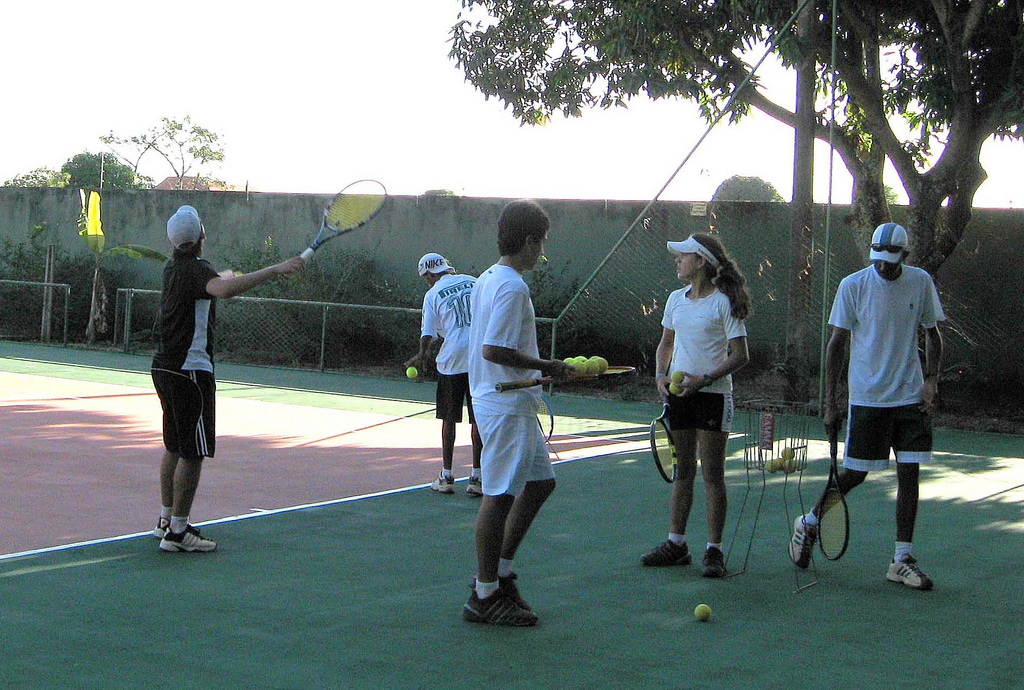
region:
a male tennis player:
[459, 199, 638, 627]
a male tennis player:
[399, 249, 479, 494]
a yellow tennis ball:
[691, 603, 712, 622]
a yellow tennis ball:
[667, 366, 684, 383]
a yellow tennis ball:
[668, 380, 681, 393]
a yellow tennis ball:
[592, 356, 606, 372]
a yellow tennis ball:
[574, 357, 588, 376]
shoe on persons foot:
[145, 509, 171, 539]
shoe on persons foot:
[454, 579, 537, 627]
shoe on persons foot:
[498, 565, 527, 607]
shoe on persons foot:
[701, 544, 728, 580]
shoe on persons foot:
[885, 549, 936, 594]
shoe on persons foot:
[429, 468, 456, 494]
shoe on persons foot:
[460, 468, 486, 500]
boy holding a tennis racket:
[151, 178, 390, 553]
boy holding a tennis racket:
[468, 200, 634, 625]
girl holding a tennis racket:
[643, 228, 745, 570]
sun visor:
[666, 235, 721, 265]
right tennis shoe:
[638, 535, 690, 568]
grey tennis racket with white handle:
[303, 178, 390, 255]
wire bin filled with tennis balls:
[724, 398, 823, 591]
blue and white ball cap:
[868, 219, 907, 262]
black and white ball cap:
[417, 252, 453, 273]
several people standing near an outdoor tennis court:
[3, 2, 1016, 688]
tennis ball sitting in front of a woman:
[640, 230, 754, 624]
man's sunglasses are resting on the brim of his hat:
[787, 222, 946, 590]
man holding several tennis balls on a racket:
[464, 200, 641, 625]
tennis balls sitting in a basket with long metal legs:
[717, 397, 822, 591]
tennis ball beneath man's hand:
[400, 252, 483, 494]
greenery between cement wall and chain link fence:
[3, 185, 1022, 433]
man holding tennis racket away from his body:
[149, 176, 388, 551]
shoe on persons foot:
[149, 519, 219, 552]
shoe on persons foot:
[148, 509, 168, 533]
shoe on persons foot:
[458, 578, 532, 629]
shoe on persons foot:
[502, 569, 528, 611]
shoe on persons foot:
[430, 464, 456, 491]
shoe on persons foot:
[697, 541, 729, 576]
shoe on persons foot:
[879, 554, 933, 596]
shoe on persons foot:
[464, 462, 488, 500]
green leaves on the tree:
[667, 40, 712, 83]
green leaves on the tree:
[509, 10, 557, 75]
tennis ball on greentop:
[693, 589, 716, 625]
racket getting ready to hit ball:
[307, 174, 393, 261]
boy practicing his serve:
[398, 247, 488, 486]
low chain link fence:
[125, 279, 556, 381]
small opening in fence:
[63, 276, 130, 362]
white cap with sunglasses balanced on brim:
[854, 216, 919, 270]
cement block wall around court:
[0, 181, 1022, 415]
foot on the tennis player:
[157, 514, 219, 552]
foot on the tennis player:
[146, 501, 169, 531]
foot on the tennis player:
[418, 462, 450, 495]